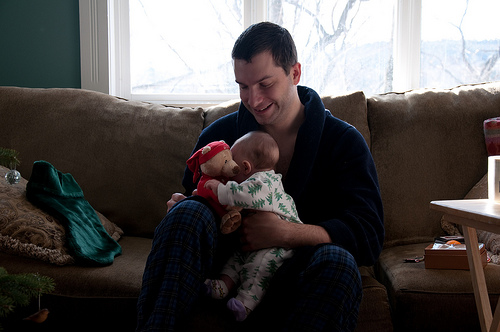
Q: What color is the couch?
A: Brown.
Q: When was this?
A: Daytime.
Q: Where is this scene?
A: Living room.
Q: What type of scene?
A: Indoor.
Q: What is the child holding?
A: A bear.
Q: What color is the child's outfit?
A: White.